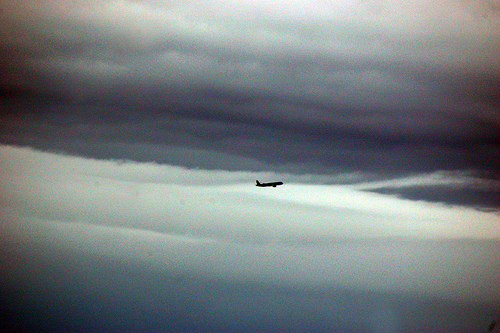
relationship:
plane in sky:
[254, 176, 285, 189] [2, 2, 499, 332]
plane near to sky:
[254, 176, 285, 189] [2, 2, 499, 332]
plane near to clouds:
[254, 176, 285, 189] [4, 2, 498, 332]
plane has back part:
[254, 176, 285, 189] [252, 178, 264, 188]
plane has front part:
[254, 176, 285, 189] [273, 179, 284, 187]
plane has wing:
[254, 176, 285, 189] [254, 178, 262, 186]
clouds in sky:
[4, 2, 498, 332] [2, 2, 499, 332]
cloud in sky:
[1, 150, 498, 260] [2, 2, 499, 332]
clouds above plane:
[4, 2, 498, 332] [254, 176, 285, 189]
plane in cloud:
[254, 176, 285, 189] [1, 150, 498, 260]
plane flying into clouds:
[254, 176, 285, 189] [4, 2, 498, 332]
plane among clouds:
[254, 176, 285, 189] [4, 2, 498, 332]